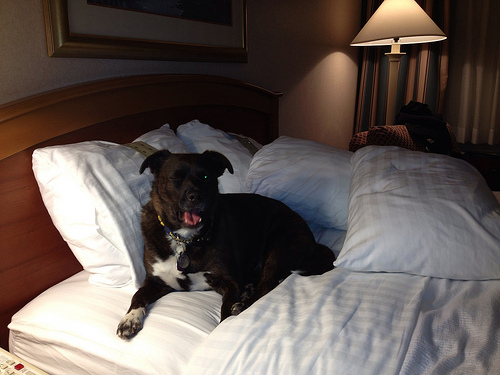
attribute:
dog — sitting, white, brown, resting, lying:
[117, 149, 337, 341]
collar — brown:
[152, 211, 219, 243]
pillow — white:
[31, 124, 194, 296]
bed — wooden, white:
[8, 117, 499, 373]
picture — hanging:
[42, 1, 252, 67]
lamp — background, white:
[350, 1, 447, 124]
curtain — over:
[351, 1, 447, 132]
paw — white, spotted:
[115, 306, 147, 340]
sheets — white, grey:
[8, 224, 346, 373]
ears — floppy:
[139, 149, 235, 177]